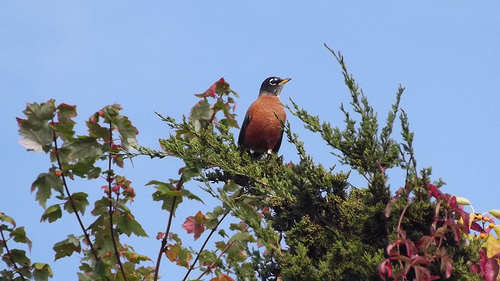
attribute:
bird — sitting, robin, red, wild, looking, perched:
[253, 71, 295, 102]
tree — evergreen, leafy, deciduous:
[210, 145, 435, 278]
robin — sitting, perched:
[243, 72, 299, 162]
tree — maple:
[20, 108, 188, 270]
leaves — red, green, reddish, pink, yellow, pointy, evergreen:
[28, 100, 72, 147]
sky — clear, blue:
[12, 15, 47, 37]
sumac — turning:
[460, 209, 497, 246]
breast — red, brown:
[268, 98, 278, 108]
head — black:
[259, 72, 290, 95]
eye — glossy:
[271, 80, 277, 84]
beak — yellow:
[277, 75, 292, 88]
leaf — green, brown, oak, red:
[74, 141, 105, 178]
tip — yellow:
[289, 79, 291, 80]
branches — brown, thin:
[211, 205, 239, 259]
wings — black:
[240, 130, 283, 156]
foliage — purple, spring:
[393, 243, 490, 280]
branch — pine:
[229, 156, 294, 191]